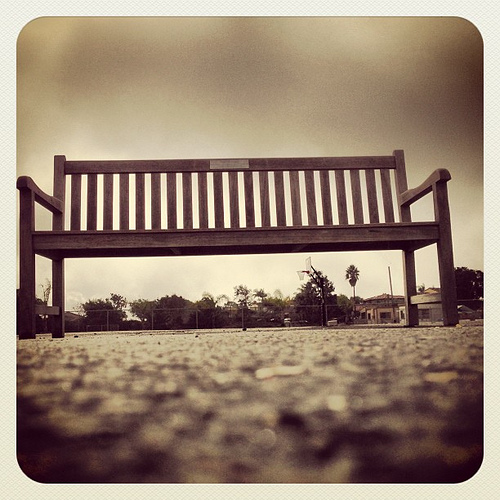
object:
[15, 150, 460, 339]
bench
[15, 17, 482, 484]
park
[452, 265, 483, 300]
trees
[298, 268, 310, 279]
basketball hoop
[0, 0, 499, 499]
picture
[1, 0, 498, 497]
black and white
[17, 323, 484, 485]
ground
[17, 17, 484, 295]
sky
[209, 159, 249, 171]
label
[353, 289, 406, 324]
structures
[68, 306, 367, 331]
fence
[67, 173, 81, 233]
slats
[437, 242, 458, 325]
leg